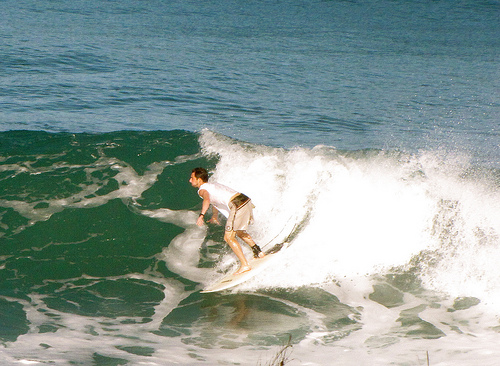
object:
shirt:
[197, 180, 239, 218]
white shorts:
[225, 193, 256, 232]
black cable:
[251, 244, 262, 256]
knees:
[224, 230, 247, 241]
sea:
[0, 0, 500, 366]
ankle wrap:
[252, 246, 261, 253]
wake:
[191, 132, 455, 292]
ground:
[387, 150, 442, 185]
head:
[189, 167, 209, 188]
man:
[189, 167, 266, 276]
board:
[199, 237, 290, 293]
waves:
[193, 129, 499, 315]